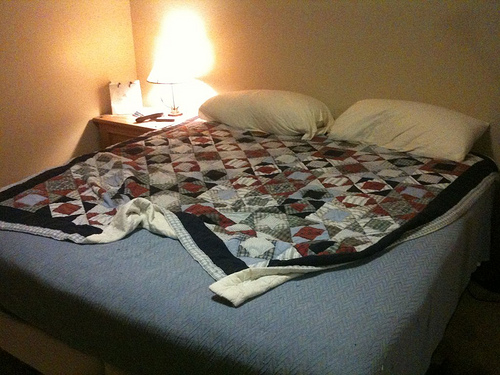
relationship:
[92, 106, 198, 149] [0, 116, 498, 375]
bedside table next to bed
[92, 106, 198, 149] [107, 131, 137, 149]
bedside table has drawer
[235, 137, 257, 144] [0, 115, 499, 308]
square stitched on quilt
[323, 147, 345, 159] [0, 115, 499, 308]
square stitched on quilt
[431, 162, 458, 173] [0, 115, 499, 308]
square stitched on quilt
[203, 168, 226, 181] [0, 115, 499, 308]
square stitched on quilt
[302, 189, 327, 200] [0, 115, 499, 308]
square stitched on quilt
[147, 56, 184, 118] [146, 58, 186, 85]
lamp has lamp shade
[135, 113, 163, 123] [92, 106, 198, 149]
remote control sitting on bedside table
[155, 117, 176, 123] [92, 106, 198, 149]
remote control sitting on bedside table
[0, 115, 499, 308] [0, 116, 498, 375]
quilt laying on bed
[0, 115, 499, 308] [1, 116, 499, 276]
quilt has lining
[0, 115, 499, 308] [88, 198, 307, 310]
quilt has bottom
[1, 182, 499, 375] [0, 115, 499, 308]
sheet below quilt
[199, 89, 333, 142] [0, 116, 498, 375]
pillow on top of bed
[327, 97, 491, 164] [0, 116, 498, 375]
pillow on top of bed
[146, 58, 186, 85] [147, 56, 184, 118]
lamp shade on top of lamp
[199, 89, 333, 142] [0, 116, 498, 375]
pillow laying on bed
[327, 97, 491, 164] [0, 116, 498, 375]
pillow laying on bed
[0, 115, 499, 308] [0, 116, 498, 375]
quilt on top of bed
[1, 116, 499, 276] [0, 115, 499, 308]
lining around quilt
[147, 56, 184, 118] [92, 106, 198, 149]
lamp sitting on bedside table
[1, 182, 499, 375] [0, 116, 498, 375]
sheet on top of bed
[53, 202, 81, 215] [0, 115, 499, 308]
square stitched on quilt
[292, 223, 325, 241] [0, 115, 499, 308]
square stitched on quilt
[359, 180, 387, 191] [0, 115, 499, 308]
square stitched on quilt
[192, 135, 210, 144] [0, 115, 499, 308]
square stitched on quilt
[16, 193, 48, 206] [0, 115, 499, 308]
square stitched on quilt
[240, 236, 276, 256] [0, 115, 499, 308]
square stitched on quilt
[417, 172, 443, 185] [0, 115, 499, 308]
square stitched on quilt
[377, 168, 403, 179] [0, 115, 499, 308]
square stitched on quilt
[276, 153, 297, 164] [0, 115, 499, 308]
square stitched on quilt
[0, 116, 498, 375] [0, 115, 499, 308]
bed has quilt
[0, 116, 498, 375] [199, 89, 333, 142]
bed has pillow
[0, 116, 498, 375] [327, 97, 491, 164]
bed has pillow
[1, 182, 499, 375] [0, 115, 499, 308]
sheet under quilt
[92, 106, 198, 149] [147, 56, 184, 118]
bedside table holds lamp